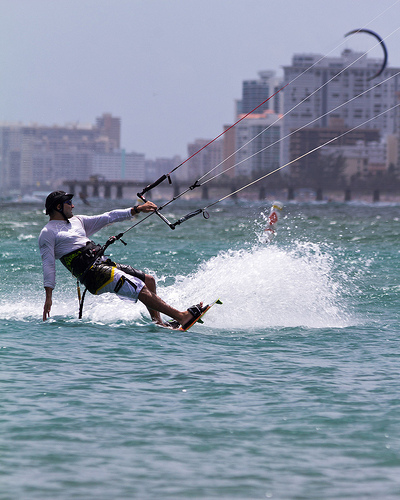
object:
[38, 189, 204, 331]
man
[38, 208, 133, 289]
shirt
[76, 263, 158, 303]
shorts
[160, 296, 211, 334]
slippers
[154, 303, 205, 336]
feet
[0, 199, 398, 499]
water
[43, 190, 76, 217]
hat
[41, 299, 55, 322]
hand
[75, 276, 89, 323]
strap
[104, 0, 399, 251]
kite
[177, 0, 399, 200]
lines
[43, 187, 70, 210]
helmet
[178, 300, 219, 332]
board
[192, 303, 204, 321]
strap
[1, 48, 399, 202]
buildings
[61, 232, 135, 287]
belt gear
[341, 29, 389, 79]
kite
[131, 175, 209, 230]
rods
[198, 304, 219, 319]
tip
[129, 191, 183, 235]
bar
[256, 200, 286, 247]
buoy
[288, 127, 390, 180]
building